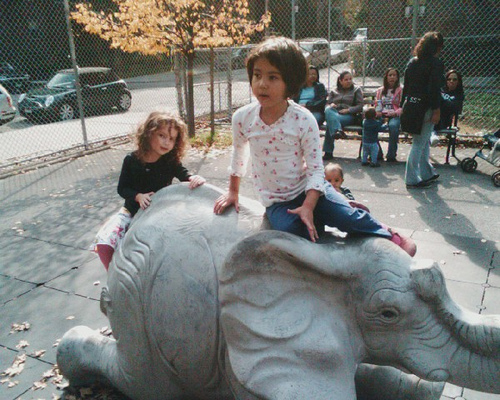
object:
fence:
[162, 4, 496, 135]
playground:
[4, 3, 498, 395]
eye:
[377, 307, 400, 321]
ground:
[456, 154, 472, 176]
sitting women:
[434, 66, 465, 133]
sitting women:
[363, 62, 402, 161]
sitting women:
[295, 63, 329, 124]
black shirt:
[116, 151, 189, 217]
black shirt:
[438, 80, 465, 128]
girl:
[95, 110, 205, 272]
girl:
[321, 70, 363, 159]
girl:
[399, 27, 445, 186]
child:
[213, 38, 416, 257]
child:
[92, 111, 207, 267]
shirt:
[298, 85, 325, 110]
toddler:
[360, 104, 382, 170]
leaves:
[67, 0, 273, 57]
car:
[296, 37, 332, 78]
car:
[16, 56, 130, 121]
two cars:
[0, 62, 133, 130]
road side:
[1, 44, 228, 119]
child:
[357, 107, 382, 167]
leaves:
[1, 302, 66, 391]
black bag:
[399, 91, 429, 136]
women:
[268, 57, 464, 154]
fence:
[1, 2, 243, 179]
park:
[0, 3, 119, 80]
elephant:
[56, 180, 499, 398]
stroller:
[459, 124, 499, 185]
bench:
[286, 79, 461, 161]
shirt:
[228, 98, 335, 206]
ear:
[218, 228, 357, 398]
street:
[0, 40, 359, 165]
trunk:
[401, 261, 499, 395]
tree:
[69, 0, 273, 135]